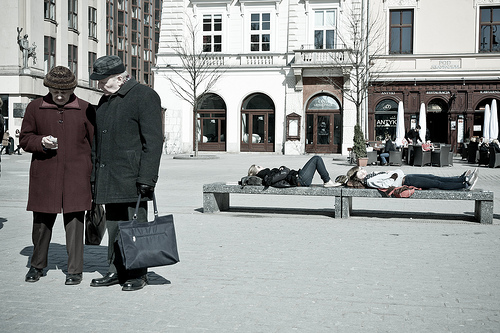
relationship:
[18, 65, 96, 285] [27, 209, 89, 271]
person wearing pants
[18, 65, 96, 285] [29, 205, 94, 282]
person wearing pants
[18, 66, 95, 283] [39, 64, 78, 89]
person with hat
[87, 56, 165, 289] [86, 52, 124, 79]
person with hat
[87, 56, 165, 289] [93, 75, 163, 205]
person with coat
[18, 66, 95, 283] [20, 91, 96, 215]
person with overcoat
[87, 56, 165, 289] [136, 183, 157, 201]
person with gloves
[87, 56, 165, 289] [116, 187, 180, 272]
person with satchel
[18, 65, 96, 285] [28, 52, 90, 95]
person with hat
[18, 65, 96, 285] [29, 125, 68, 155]
person looking at something in hand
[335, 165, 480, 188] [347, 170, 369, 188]
people with hair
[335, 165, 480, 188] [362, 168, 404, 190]
people lying down with jacket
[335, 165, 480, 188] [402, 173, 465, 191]
people lying down with pants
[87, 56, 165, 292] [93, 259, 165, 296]
person wearing shoes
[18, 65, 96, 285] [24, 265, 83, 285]
person wearing shoes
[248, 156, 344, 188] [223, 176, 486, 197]
girl laying on grass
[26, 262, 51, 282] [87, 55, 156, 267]
shoes on person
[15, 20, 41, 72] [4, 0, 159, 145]
sculpture on building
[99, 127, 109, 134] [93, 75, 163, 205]
button on coat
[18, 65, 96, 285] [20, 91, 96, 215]
person wearing overcoat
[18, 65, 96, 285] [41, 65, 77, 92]
person wearing hat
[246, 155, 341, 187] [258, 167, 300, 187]
girl wearing jacket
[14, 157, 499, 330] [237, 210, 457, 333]
paved area of a square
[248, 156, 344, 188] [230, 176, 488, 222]
girl on grass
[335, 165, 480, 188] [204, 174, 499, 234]
people on grass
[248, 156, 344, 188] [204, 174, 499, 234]
girl on grass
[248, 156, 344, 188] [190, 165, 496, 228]
girl on grass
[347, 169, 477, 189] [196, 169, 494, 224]
people on grass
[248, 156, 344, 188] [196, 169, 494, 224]
girl on grass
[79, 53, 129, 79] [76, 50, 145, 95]
hat on head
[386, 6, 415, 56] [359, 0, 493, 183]
window on building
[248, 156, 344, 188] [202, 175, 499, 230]
girl on benches